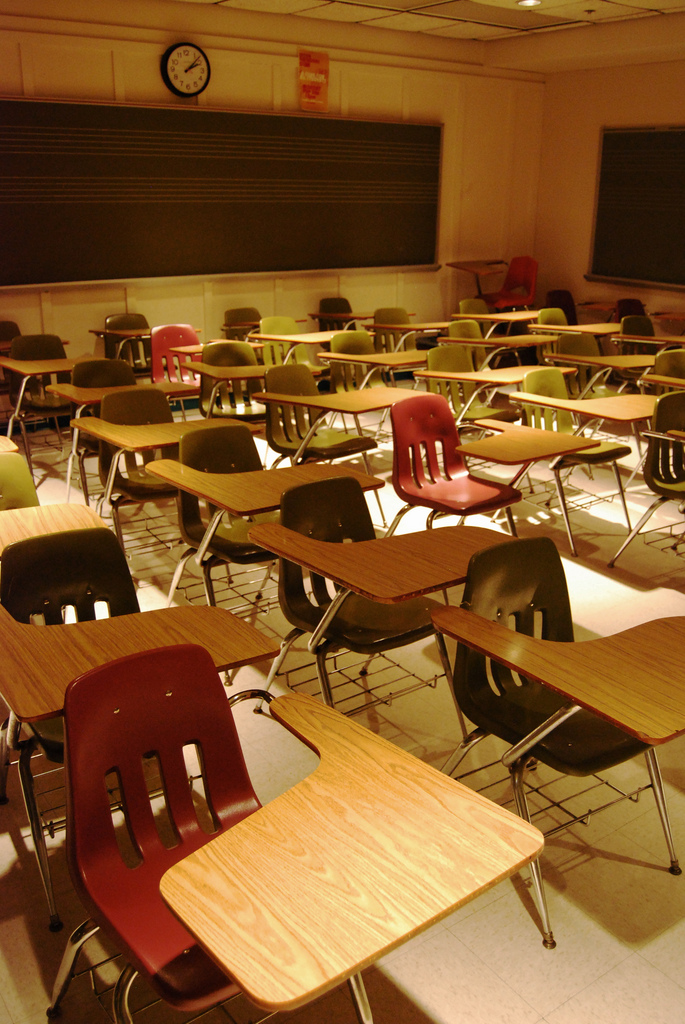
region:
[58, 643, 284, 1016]
chair color is red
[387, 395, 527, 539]
chair color is red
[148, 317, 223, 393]
chair color is red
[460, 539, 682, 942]
chair color is black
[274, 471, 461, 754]
chair color is black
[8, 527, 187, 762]
chair color is black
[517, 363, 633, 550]
chair color is green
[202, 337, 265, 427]
chair color is green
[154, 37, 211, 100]
clock hanging above board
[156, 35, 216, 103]
clock is black and white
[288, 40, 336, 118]
sign hanging above board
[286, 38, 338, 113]
sign is orange and red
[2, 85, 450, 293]
board hanging on wall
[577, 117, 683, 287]
chalkboard on right wall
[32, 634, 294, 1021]
front desk chair is red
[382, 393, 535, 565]
middle desk chair is red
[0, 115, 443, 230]
lines on chalk board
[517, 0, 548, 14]
small light in ceiling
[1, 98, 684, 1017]
An empty classroom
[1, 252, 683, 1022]
Desks in the classroom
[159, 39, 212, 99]
A clock on the wall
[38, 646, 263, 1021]
Red chair attached to the front desk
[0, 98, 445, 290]
Blackboard on the back wall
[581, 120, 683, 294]
Blackboard on the right wall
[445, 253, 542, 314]
One desk in the corner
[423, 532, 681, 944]
Desk with a black chair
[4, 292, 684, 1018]
Rows of desks in the classroom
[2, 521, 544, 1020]
Two desks in the first row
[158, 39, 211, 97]
black and white clock on the wall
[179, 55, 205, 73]
black minute and hour hands on the clock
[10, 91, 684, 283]
blackboards on the wall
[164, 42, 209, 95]
black numbers on the clock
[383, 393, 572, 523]
desk with red chair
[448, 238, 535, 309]
desk in the corner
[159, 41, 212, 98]
round clock on the wall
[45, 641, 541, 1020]
writing desk combined with a red chair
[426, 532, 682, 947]
writing desk combined with a black chair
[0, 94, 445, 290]
blackboard under the clock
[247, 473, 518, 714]
writing desk combined with a black chair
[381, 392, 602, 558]
writing desk combined with a red chair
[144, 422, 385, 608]
writing desk combined with a black chair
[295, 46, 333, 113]
orange poster above the blackboard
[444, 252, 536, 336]
writing desk combined with a red chair in the corner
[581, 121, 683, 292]
partly visible blackboard on the wall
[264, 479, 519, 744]
empty desk in the classroom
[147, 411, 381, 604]
empty desk in the classroom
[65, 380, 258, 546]
empty desk in the classroom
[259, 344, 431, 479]
empty desk in the classroom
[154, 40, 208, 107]
white colored clock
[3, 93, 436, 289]
black colored chalkboard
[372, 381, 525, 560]
A chair that you sit in.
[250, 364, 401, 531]
A chair that you sit in.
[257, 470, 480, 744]
A chair that you sit in.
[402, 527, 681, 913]
A chair that you sit in.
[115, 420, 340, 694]
A chair that you sit in.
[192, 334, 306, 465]
A chair that you sit in.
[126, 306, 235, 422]
A chair that you sit in.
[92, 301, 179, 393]
A chair that you sit in.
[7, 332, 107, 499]
A chair that you sit in.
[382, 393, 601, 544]
red school desk next to green school desk